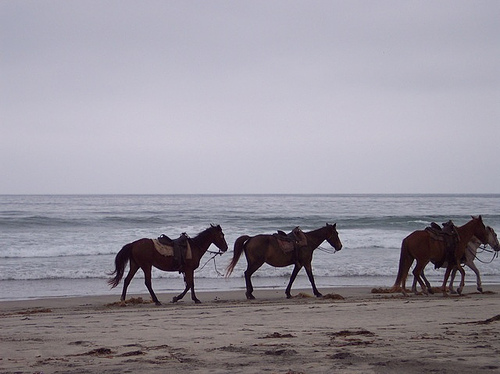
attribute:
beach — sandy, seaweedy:
[0, 282, 499, 371]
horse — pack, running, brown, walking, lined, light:
[227, 223, 342, 303]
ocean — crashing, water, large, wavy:
[2, 195, 500, 279]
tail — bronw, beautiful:
[224, 234, 252, 276]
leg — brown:
[303, 259, 323, 297]